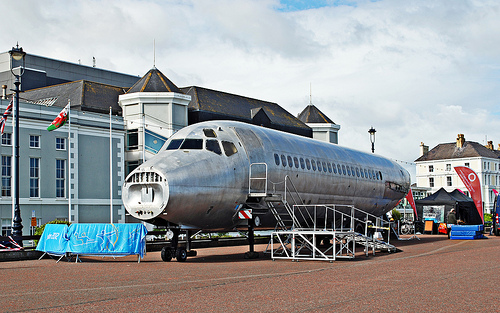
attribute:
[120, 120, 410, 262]
airplane — big, silver, old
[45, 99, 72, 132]
flag — welsh, red, green, white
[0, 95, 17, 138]
union jack — wave, flying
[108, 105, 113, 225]
pole — flagless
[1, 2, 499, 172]
day — cloudy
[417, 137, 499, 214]
building — white, yellow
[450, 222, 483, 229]
box — blue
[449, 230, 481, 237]
box — blue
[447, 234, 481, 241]
box — blue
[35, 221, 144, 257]
sign — blue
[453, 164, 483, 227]
sign — red, standing, white, tall, narrow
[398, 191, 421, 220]
sign — red, standing, white, tall, narrow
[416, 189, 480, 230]
tent — black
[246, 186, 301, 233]
steps — silver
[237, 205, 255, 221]
sign — red, white, striped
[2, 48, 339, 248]
building — pale blue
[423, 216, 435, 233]
sign — orange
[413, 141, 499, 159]
roof — brown